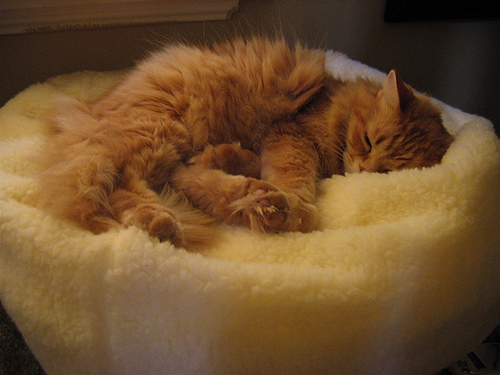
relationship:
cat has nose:
[47, 30, 462, 245] [356, 163, 376, 173]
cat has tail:
[47, 27, 455, 246] [48, 95, 104, 217]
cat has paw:
[47, 30, 462, 245] [136, 206, 179, 240]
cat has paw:
[47, 30, 462, 245] [228, 170, 333, 240]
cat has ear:
[47, 30, 462, 245] [381, 69, 409, 106]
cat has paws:
[47, 27, 455, 246] [128, 203, 193, 243]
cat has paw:
[47, 27, 455, 246] [244, 190, 316, 229]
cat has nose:
[47, 27, 455, 246] [356, 162, 372, 175]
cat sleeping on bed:
[47, 30, 462, 245] [0, 43, 498, 372]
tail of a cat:
[33, 99, 222, 255] [47, 30, 462, 245]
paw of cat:
[136, 206, 181, 248] [54, 18, 449, 253]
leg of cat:
[263, 127, 321, 195] [47, 30, 462, 245]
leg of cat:
[175, 159, 284, 233] [47, 30, 462, 245]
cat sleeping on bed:
[47, 27, 455, 246] [0, 53, 493, 346]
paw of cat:
[136, 206, 179, 240] [47, 27, 455, 246]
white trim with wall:
[0, 0, 241, 38] [5, 9, 498, 143]